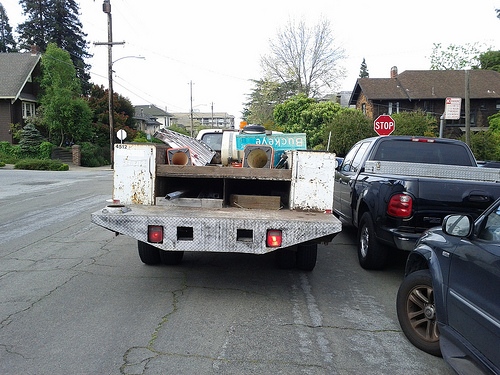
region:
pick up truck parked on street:
[348, 142, 425, 266]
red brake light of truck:
[387, 182, 422, 243]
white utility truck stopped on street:
[143, 145, 295, 230]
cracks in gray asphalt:
[157, 293, 224, 369]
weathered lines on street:
[286, 286, 306, 361]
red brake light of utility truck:
[258, 229, 314, 267]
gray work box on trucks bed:
[366, 153, 462, 202]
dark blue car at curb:
[423, 245, 491, 337]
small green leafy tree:
[52, 94, 96, 151]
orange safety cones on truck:
[171, 125, 286, 175]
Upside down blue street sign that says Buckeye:
[234, 129, 311, 156]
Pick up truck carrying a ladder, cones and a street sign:
[91, 117, 351, 280]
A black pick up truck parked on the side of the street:
[327, 129, 498, 273]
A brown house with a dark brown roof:
[350, 60, 498, 167]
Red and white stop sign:
[367, 109, 401, 140]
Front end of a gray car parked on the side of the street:
[396, 173, 496, 373]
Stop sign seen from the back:
[113, 125, 130, 151]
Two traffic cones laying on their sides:
[163, 140, 274, 176]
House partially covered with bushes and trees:
[1, 36, 84, 173]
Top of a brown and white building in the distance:
[167, 106, 235, 133]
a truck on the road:
[97, 105, 347, 272]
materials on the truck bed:
[160, 123, 314, 205]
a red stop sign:
[370, 112, 396, 138]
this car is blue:
[392, 197, 492, 373]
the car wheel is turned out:
[389, 245, 449, 359]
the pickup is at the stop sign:
[324, 124, 499, 267]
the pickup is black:
[318, 129, 498, 269]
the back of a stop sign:
[114, 128, 129, 144]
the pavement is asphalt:
[9, 162, 494, 365]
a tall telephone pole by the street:
[93, 2, 128, 167]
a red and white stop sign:
[362, 103, 410, 137]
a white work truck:
[93, 124, 349, 276]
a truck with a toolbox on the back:
[332, 127, 490, 271]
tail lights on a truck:
[129, 210, 322, 257]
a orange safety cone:
[153, 141, 200, 178]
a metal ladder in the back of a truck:
[156, 126, 219, 172]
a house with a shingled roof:
[346, 68, 473, 113]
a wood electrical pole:
[83, 4, 128, 156]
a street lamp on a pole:
[83, 34, 155, 135]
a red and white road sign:
[438, 87, 467, 129]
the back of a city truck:
[88, 128, 343, 269]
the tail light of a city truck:
[261, 224, 285, 249]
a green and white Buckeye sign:
[236, 128, 307, 173]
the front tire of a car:
[390, 262, 450, 364]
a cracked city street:
[7, 232, 405, 370]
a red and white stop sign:
[370, 110, 396, 137]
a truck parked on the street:
[325, 121, 495, 280]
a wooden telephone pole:
[80, 0, 129, 164]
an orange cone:
[241, 140, 276, 173]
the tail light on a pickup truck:
[386, 186, 416, 223]